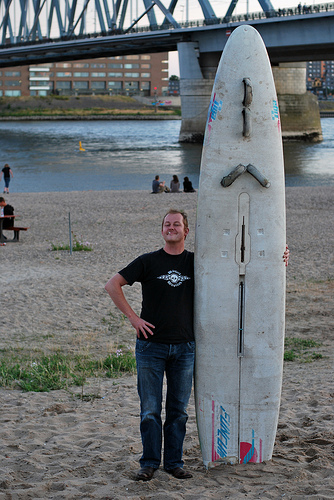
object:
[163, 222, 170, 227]
eye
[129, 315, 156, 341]
hand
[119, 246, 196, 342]
shirt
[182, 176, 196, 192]
people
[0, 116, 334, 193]
river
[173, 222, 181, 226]
eye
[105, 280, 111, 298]
elbow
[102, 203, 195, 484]
man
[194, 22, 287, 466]
board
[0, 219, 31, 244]
table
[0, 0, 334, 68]
bridge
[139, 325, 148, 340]
finger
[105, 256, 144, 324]
arm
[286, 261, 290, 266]
finger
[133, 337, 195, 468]
jeans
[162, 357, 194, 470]
leg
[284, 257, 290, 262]
fingers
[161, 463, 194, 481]
feet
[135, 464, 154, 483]
feet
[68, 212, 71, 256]
pipe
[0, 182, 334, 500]
sand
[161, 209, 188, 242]
head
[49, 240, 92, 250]
grass patch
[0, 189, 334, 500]
ground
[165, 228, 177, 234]
mouth